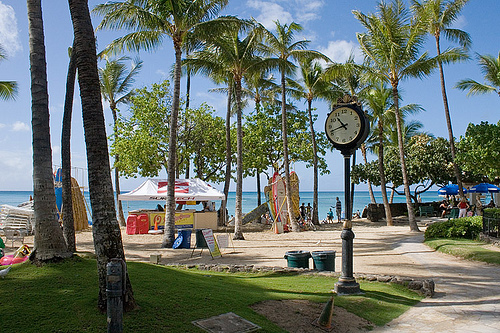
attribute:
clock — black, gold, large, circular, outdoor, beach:
[324, 97, 372, 294]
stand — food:
[115, 175, 228, 232]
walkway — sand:
[318, 235, 484, 331]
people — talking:
[434, 196, 484, 217]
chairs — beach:
[0, 200, 37, 253]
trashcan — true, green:
[282, 247, 337, 273]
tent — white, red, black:
[114, 176, 226, 203]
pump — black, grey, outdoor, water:
[102, 250, 130, 330]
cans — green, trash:
[284, 248, 338, 270]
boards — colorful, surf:
[264, 169, 301, 229]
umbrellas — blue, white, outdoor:
[437, 178, 484, 199]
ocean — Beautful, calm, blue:
[0, 189, 493, 219]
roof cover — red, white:
[117, 179, 226, 201]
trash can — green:
[311, 249, 336, 272]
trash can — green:
[284, 250, 309, 268]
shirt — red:
[457, 201, 467, 207]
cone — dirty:
[309, 294, 336, 329]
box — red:
[135, 213, 149, 234]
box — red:
[127, 211, 137, 233]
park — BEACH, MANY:
[5, 17, 455, 327]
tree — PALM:
[374, 1, 430, 211]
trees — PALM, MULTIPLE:
[148, 18, 298, 164]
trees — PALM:
[152, 1, 258, 85]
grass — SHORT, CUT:
[169, 267, 214, 305]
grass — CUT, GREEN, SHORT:
[176, 269, 207, 303]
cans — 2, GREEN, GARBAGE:
[288, 249, 330, 269]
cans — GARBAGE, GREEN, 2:
[283, 230, 342, 270]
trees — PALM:
[173, 12, 463, 96]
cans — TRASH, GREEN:
[285, 248, 342, 266]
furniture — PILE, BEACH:
[5, 196, 36, 238]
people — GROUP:
[432, 195, 471, 220]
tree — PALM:
[61, 1, 141, 251]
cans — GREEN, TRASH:
[286, 240, 338, 275]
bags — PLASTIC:
[288, 245, 300, 255]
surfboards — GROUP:
[266, 162, 305, 224]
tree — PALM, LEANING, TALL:
[410, 10, 480, 196]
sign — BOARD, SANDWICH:
[154, 203, 207, 223]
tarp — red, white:
[118, 175, 227, 204]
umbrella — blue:
[437, 179, 467, 210]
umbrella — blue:
[462, 174, 484, 198]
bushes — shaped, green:
[425, 211, 481, 243]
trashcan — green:
[310, 250, 340, 278]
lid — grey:
[308, 245, 338, 257]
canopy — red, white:
[120, 176, 225, 208]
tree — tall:
[57, 3, 142, 331]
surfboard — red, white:
[270, 172, 290, 230]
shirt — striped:
[334, 201, 342, 214]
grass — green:
[159, 273, 243, 305]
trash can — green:
[282, 249, 310, 273]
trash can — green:
[310, 245, 338, 272]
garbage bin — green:
[278, 246, 310, 274]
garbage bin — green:
[307, 247, 338, 273]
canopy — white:
[120, 176, 227, 205]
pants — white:
[454, 206, 468, 220]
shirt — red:
[452, 198, 467, 209]